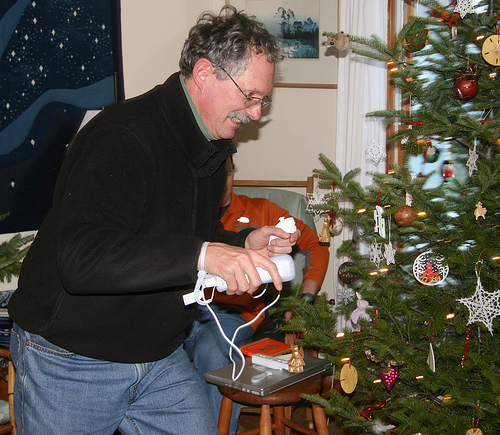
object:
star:
[382, 240, 400, 264]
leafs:
[415, 287, 441, 307]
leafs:
[361, 337, 383, 353]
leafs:
[466, 352, 488, 369]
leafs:
[472, 236, 488, 262]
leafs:
[393, 396, 422, 412]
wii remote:
[181, 252, 289, 302]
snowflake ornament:
[466, 139, 481, 176]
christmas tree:
[270, 0, 499, 435]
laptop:
[204, 350, 334, 397]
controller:
[251, 353, 294, 372]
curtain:
[332, 0, 398, 331]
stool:
[216, 374, 331, 435]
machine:
[199, 253, 295, 291]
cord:
[195, 283, 281, 382]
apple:
[455, 77, 481, 100]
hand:
[207, 246, 283, 296]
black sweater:
[4, 70, 257, 364]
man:
[7, 5, 300, 435]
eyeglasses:
[217, 65, 272, 111]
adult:
[8, 7, 301, 435]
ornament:
[374, 359, 417, 391]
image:
[224, 0, 319, 59]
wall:
[118, 0, 340, 316]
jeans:
[9, 321, 217, 432]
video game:
[189, 214, 306, 378]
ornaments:
[306, 192, 335, 243]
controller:
[269, 217, 297, 253]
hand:
[245, 226, 301, 259]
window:
[369, 7, 497, 317]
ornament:
[412, 252, 451, 285]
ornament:
[455, 267, 499, 341]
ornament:
[337, 356, 359, 397]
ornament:
[447, 67, 480, 107]